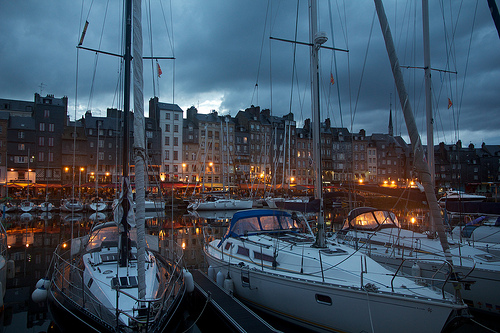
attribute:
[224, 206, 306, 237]
cover — blue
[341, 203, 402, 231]
cover — blue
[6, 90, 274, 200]
building — large, dark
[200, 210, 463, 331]
boat — white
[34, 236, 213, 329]
railing — silver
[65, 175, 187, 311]
sailboat — docked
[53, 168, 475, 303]
boats — docked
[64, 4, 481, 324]
masts — tall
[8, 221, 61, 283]
water surface — calm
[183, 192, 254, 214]
boat — seaworthy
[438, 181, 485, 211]
boat — seaworthy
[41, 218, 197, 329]
boat — seaworthy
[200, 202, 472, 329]
boat — seaworthy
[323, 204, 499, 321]
boat — seaworthy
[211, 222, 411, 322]
boat — docked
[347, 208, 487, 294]
boat — docked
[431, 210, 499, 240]
boat — docked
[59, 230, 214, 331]
boat — docked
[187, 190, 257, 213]
boat — docked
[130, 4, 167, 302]
canvas — white, rolled-up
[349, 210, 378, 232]
window — lit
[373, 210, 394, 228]
window — lit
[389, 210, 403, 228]
window — lit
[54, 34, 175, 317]
boats — docked